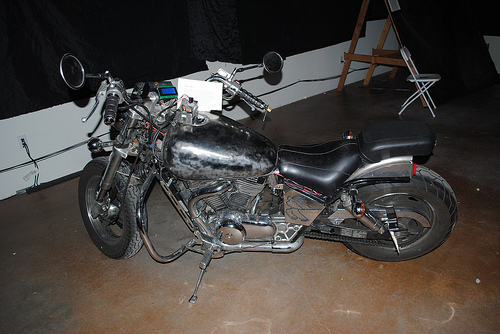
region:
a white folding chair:
[397, 47, 445, 123]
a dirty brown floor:
[0, 67, 498, 332]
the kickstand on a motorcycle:
[183, 250, 213, 312]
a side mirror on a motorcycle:
[261, 51, 290, 75]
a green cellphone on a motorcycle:
[156, 83, 181, 103]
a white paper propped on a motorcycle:
[174, 75, 230, 120]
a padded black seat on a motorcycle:
[270, 132, 361, 193]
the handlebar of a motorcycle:
[81, 75, 120, 126]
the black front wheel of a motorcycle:
[78, 154, 147, 261]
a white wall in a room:
[0, 14, 399, 201]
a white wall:
[0, 0, 398, 200]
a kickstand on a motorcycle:
[183, 246, 218, 307]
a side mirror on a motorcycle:
[50, 50, 110, 86]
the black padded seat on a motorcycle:
[266, 130, 361, 195]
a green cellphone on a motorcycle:
[152, 80, 174, 100]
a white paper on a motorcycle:
[170, 75, 220, 116]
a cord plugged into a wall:
[19, 137, 44, 190]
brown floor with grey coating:
[5, 50, 491, 325]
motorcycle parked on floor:
[55, 50, 455, 302]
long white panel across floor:
[0, 16, 395, 196]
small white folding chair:
[391, 45, 437, 115]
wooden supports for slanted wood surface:
[335, 5, 495, 100]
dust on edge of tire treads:
[77, 155, 147, 257]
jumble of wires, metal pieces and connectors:
[120, 87, 180, 157]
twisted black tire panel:
[346, 152, 412, 182]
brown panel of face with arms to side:
[280, 185, 325, 225]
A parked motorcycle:
[197, 154, 413, 239]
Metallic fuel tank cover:
[197, 135, 244, 170]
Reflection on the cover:
[195, 149, 205, 154]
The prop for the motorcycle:
[192, 298, 195, 302]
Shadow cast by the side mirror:
[80, 101, 85, 104]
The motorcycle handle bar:
[108, 103, 112, 118]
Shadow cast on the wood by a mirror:
[269, 75, 279, 81]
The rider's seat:
[300, 151, 337, 166]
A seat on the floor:
[414, 75, 438, 79]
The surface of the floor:
[360, 266, 447, 321]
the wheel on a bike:
[65, 153, 170, 262]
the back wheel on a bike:
[326, 137, 464, 273]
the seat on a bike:
[232, 115, 375, 233]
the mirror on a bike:
[39, 47, 125, 124]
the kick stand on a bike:
[164, 203, 276, 311]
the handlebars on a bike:
[91, 48, 300, 165]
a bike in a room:
[82, 52, 400, 264]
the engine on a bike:
[168, 155, 308, 251]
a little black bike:
[78, 43, 475, 256]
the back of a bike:
[309, 111, 497, 267]